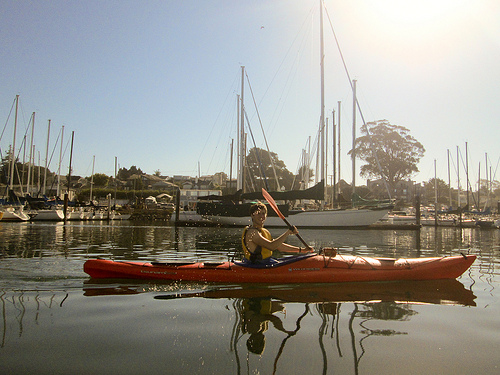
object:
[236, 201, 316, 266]
man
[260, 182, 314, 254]
rowing stick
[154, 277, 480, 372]
shadow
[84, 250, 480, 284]
boat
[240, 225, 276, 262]
jacket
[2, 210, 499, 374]
water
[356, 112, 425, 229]
tree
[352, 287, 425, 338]
shadow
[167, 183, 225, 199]
building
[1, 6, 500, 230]
background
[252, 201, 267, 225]
head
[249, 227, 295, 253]
arm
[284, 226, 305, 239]
hand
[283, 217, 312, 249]
handle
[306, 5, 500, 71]
sun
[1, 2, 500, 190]
sky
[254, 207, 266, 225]
face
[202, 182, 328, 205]
sail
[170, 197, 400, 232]
boat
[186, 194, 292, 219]
mask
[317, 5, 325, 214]
pole